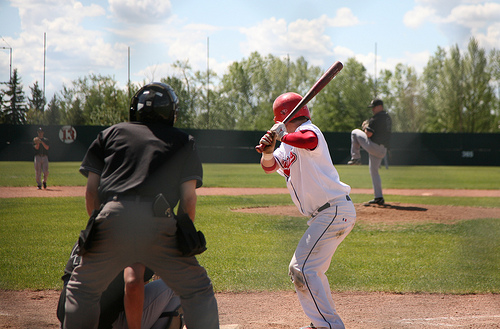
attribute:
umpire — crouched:
[54, 72, 229, 313]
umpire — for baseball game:
[32, 61, 227, 326]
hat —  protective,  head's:
[121, 81, 187, 123]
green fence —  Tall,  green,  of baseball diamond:
[7, 105, 497, 180]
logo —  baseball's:
[54, 119, 84, 145]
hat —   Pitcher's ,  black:
[364, 94, 386, 109]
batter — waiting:
[253, 88, 358, 327]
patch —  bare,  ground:
[391, 305, 428, 312]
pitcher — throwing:
[348, 98, 397, 204]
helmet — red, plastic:
[266, 90, 313, 124]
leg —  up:
[346, 126, 365, 163]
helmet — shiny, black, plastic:
[126, 80, 179, 125]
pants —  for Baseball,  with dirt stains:
[287, 197, 358, 327]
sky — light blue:
[282, 0, 407, 52]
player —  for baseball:
[237, 74, 393, 274]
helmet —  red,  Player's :
[269, 80, 305, 121]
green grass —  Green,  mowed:
[1, 190, 498, 305]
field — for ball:
[3, 115, 498, 327]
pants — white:
[280, 216, 365, 326]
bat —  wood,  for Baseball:
[254, 59, 344, 155]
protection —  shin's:
[167, 309, 184, 327]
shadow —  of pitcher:
[385, 203, 431, 211]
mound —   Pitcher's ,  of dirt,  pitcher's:
[223, 198, 497, 223]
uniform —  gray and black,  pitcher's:
[345, 107, 392, 200]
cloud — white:
[0, 1, 498, 97]